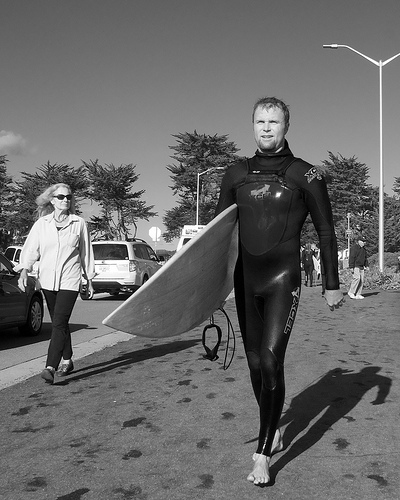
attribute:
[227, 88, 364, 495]
man — with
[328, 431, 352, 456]
footprints — on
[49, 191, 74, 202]
sunglasses — on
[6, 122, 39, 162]
cloud — in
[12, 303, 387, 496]
footprints — wet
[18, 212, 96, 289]
shirt — button down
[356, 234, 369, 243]
cap — baseball cap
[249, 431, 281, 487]
feet — bare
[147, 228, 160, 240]
sign — silver, octagon shaped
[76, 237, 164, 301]
utility vehicles — white, sport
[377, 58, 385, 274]
pole — metal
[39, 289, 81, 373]
pants — dark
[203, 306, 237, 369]
leash — black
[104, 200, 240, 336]
surfboard — large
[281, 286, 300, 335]
logo — white, printed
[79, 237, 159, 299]
vehicle — white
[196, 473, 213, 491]
spot — dark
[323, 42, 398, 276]
lamp post — tall, metal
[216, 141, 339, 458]
wetsuit — black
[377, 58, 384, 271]
post — thin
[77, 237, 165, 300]
suv — white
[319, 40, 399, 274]
light — tall, metal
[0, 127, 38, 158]
cloud — small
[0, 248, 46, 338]
car — dark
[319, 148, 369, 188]
leaves — green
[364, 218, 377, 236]
leaves — green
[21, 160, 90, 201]
leaves — green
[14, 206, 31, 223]
leaves — green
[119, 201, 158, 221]
leaves — green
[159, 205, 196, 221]
leaves — green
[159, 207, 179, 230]
leaves — green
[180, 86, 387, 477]
surfer — shadow 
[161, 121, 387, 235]
trees — background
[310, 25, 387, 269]
light — street 